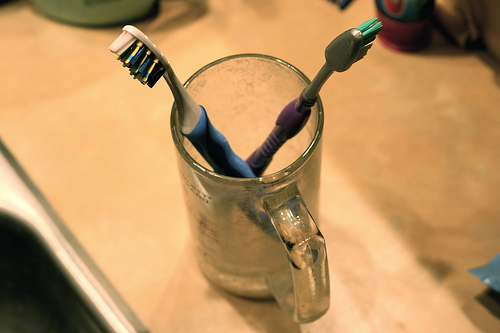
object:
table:
[0, 0, 500, 332]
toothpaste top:
[362, 17, 387, 59]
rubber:
[283, 110, 296, 125]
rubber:
[179, 104, 282, 241]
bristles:
[354, 17, 384, 63]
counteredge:
[0, 136, 145, 333]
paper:
[465, 250, 499, 285]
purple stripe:
[260, 130, 279, 155]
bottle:
[373, 0, 483, 57]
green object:
[29, 0, 174, 26]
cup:
[169, 53, 332, 323]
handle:
[262, 182, 331, 324]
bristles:
[107, 30, 166, 88]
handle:
[245, 98, 312, 177]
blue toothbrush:
[107, 22, 282, 238]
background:
[0, 0, 497, 329]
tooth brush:
[241, 17, 383, 177]